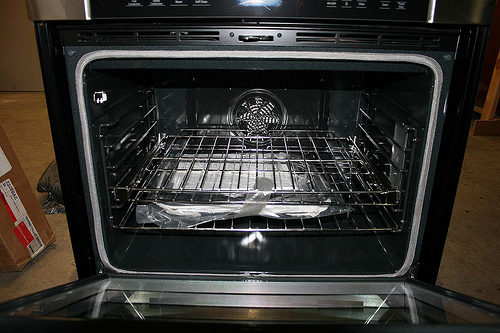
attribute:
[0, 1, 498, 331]
oven — black, open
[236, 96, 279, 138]
fan — small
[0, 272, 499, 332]
door — open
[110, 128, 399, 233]
racks — silver, steel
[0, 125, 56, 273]
cardboard box — brown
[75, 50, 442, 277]
seal — gray